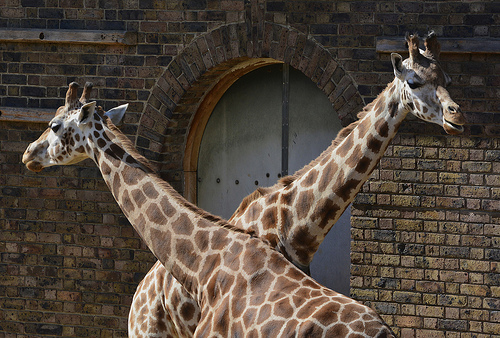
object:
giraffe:
[22, 81, 399, 337]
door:
[194, 63, 351, 295]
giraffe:
[126, 30, 467, 336]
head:
[21, 81, 130, 173]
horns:
[64, 81, 81, 107]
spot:
[151, 225, 171, 267]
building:
[0, 0, 499, 337]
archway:
[133, 14, 367, 298]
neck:
[89, 109, 252, 296]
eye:
[50, 123, 63, 132]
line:
[0, 29, 125, 46]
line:
[1, 106, 57, 123]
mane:
[97, 107, 242, 232]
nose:
[21, 144, 34, 156]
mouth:
[21, 153, 47, 173]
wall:
[377, 166, 499, 337]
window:
[185, 58, 355, 336]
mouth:
[441, 113, 464, 135]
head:
[390, 29, 466, 135]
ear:
[76, 100, 97, 127]